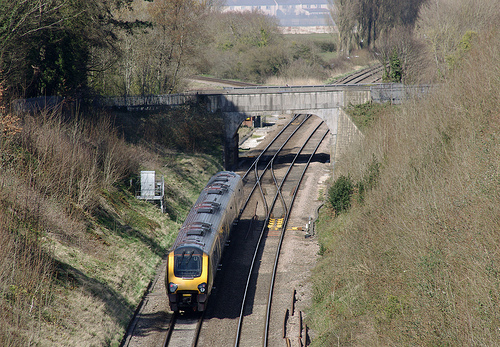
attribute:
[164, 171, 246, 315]
train — black, yellow, silver, here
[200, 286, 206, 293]
light — white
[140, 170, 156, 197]
box — silver, grey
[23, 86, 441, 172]
bridge — grey, white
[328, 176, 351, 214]
bush — green, here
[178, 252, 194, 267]
wipers — black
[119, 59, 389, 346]
tracks — here, brown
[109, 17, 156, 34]
leaves — green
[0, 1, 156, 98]
tree — large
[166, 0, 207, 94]
tree — brown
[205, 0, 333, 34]
town — here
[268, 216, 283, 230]
spot — yellow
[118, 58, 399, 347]
gravel — brown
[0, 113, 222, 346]
weeds — brown, green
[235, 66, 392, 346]
track — empty